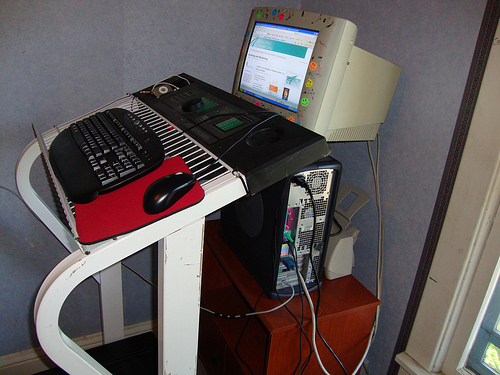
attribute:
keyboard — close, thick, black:
[53, 105, 156, 202]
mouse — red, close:
[141, 167, 197, 220]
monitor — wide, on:
[236, 0, 404, 144]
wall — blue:
[1, 4, 480, 374]